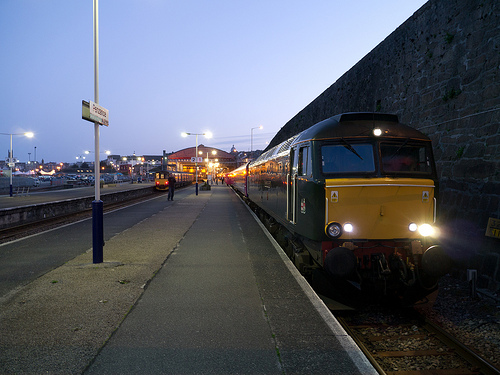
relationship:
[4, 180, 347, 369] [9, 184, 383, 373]
concrete in platform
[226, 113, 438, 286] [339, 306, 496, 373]
train on tracks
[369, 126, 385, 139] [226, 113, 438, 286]
light on train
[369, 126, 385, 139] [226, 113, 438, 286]
light on front of train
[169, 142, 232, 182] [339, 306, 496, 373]
station next to tracks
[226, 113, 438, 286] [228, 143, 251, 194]
train pulling cars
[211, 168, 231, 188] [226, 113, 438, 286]
people waiting to board train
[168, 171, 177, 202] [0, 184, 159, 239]
man standing alone near tracks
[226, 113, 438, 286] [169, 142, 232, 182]
train leaving station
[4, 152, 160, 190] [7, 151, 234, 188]
city in background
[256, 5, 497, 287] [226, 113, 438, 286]
wall next to train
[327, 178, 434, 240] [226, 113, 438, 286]
yellow front of train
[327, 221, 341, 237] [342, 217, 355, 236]
headlight next to smaller light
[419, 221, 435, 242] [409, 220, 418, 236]
headlight next to smaller light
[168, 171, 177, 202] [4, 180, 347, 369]
man standing on sidewalk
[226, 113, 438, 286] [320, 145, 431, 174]
train front windows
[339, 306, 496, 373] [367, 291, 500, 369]
tracks with gravel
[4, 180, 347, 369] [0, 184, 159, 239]
sidewalk alongside train track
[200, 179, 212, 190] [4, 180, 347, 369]
grass between two sidewalks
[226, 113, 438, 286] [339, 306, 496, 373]
train on track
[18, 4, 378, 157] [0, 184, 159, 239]
sky above track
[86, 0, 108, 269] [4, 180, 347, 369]
pole in middle of platform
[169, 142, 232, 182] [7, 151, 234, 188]
station in background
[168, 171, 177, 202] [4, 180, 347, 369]
man standing on platform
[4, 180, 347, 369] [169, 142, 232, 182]
platform in middle of station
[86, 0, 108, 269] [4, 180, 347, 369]
poles in middle of platform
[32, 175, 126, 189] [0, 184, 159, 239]
lot next to train tracks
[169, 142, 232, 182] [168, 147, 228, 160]
station has a red roof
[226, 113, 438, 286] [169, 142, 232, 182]
train has left station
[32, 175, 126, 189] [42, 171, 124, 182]
lot full of cars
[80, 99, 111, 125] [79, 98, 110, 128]
white and blue sign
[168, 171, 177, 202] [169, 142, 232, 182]
person waits at station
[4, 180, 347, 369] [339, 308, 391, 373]
divider between both tracks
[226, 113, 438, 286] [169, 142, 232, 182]
train at station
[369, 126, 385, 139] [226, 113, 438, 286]
light in front of train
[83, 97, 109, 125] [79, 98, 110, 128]
blue in a white sign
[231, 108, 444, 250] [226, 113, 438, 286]
black passenger train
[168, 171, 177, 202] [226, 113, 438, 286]
person waiting for train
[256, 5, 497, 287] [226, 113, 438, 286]
wall beside train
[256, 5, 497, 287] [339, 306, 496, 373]
wall beside tracks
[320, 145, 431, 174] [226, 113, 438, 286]
windows on front of train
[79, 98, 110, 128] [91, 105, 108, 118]
sign with letters